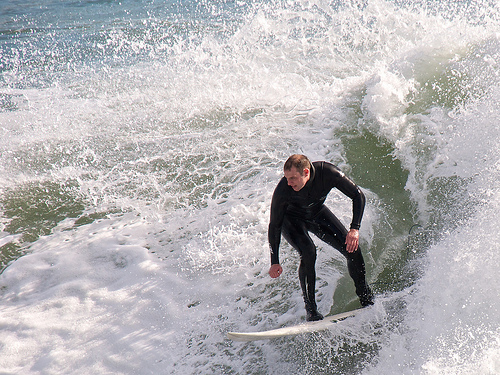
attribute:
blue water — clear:
[4, 4, 140, 64]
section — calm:
[2, 1, 209, 40]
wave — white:
[9, 37, 498, 372]